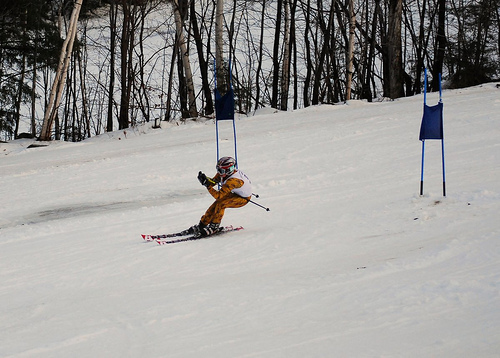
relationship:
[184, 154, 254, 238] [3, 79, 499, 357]
kid on slope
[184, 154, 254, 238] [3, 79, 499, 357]
kid going slope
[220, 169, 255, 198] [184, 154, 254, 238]
vest on kid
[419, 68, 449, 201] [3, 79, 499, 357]
flag on hill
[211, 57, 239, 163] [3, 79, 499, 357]
flag on hill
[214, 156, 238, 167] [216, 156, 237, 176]
helmet on head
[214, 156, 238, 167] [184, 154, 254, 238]
helmet on kid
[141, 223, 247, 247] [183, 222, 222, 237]
skis on feet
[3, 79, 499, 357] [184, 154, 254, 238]
hill for kid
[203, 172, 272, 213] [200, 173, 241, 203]
ski poles under arms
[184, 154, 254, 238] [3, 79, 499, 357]
kid goes down hill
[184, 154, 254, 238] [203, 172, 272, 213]
kid has poles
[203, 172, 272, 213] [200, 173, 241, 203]
poles under arms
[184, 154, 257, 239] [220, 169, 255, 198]
kid wears vest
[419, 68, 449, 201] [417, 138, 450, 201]
sign on poles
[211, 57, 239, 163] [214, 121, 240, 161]
sign on poles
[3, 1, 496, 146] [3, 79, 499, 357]
trees on top of hill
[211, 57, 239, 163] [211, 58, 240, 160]
sign on left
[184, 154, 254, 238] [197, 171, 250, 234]
kid wears snow suit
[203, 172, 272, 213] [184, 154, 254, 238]
pair for kid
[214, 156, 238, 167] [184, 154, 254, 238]
hemet for kid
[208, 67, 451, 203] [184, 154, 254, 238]
gate for kid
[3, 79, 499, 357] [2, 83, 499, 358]
slope covered in snow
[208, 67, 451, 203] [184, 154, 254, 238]
slalom gate behind kid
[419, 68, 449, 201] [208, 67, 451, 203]
flag on slalom gate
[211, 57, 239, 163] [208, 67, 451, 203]
flag on slalom gate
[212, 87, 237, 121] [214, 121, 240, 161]
sign held by sticks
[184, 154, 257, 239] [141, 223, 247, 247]
boy has skies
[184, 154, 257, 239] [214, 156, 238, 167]
boy wears helmet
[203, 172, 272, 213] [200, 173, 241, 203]
snow poles under arms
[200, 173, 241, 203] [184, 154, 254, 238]
arms of kid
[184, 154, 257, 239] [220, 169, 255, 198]
boy wears vest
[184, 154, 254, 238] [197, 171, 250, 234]
kid has winter suit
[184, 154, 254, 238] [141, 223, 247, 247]
kid on skis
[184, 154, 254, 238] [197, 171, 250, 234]
kid wearing yellow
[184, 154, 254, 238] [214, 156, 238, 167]
kid wears helmet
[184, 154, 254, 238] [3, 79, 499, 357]
kid going downhill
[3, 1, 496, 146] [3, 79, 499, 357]
trees along ski trail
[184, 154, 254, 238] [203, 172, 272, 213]
kid holds ski poles